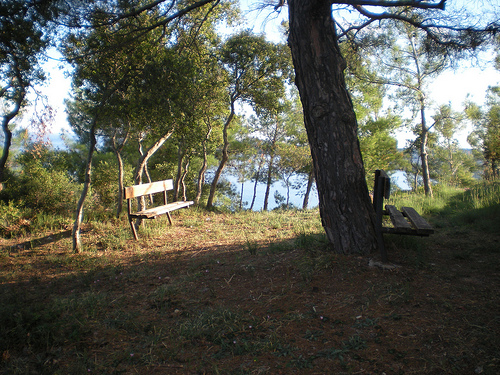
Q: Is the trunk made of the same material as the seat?
A: Yes, both the trunk and the seat are made of wood.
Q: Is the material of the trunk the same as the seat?
A: Yes, both the trunk and the seat are made of wood.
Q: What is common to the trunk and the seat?
A: The material, both the trunk and the seat are wooden.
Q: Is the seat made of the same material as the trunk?
A: Yes, both the seat and the trunk are made of wood.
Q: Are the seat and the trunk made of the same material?
A: Yes, both the seat and the trunk are made of wood.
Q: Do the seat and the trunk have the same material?
A: Yes, both the seat and the trunk are made of wood.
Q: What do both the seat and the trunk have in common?
A: The material, both the seat and the trunk are wooden.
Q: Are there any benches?
A: Yes, there is a bench.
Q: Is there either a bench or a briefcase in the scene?
A: Yes, there is a bench.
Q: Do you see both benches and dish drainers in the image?
A: No, there is a bench but no dish drainers.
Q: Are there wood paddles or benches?
A: Yes, there is a wood bench.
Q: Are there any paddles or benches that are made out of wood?
A: Yes, the bench is made of wood.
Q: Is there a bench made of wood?
A: Yes, there is a bench that is made of wood.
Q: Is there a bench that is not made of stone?
A: Yes, there is a bench that is made of wood.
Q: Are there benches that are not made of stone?
A: Yes, there is a bench that is made of wood.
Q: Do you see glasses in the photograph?
A: No, there are no glasses.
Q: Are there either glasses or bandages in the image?
A: No, there are no glasses or bandages.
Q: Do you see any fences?
A: No, there are no fences.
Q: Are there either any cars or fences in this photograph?
A: No, there are no fences or cars.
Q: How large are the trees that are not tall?
A: The trees are small.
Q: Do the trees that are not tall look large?
A: No, the trees are small.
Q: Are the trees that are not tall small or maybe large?
A: The trees are small.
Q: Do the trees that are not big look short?
A: Yes, the trees are short.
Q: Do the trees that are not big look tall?
A: No, the trees are short.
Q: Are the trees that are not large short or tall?
A: The trees are short.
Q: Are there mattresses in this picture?
A: No, there are no mattresses.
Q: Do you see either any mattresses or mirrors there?
A: No, there are no mattresses or mirrors.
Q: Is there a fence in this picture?
A: No, there are no fences.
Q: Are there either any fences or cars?
A: No, there are no fences or cars.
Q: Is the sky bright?
A: Yes, the sky is bright.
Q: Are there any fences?
A: No, there are no fences.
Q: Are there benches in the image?
A: Yes, there is a bench.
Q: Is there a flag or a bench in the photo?
A: Yes, there is a bench.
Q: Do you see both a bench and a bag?
A: No, there is a bench but no bags.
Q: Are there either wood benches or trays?
A: Yes, there is a wood bench.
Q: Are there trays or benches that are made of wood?
A: Yes, the bench is made of wood.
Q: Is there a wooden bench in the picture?
A: Yes, there is a wood bench.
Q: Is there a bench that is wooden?
A: Yes, there is a bench that is wooden.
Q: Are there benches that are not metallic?
A: Yes, there is a wooden bench.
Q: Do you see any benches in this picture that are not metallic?
A: Yes, there is a wooden bench.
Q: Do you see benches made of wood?
A: Yes, there is a bench that is made of wood.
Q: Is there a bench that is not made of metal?
A: Yes, there is a bench that is made of wood.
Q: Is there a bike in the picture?
A: No, there are no bikes.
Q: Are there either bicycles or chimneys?
A: No, there are no bicycles or chimneys.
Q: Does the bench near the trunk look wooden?
A: Yes, the bench is wooden.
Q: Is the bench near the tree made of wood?
A: Yes, the bench is made of wood.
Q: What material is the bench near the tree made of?
A: The bench is made of wood.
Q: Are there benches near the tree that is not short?
A: Yes, there is a bench near the tree.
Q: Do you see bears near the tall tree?
A: No, there is a bench near the tree.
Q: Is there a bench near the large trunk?
A: Yes, there is a bench near the trunk.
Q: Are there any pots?
A: No, there are no pots.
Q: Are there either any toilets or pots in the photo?
A: No, there are no pots or toilets.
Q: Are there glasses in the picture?
A: No, there are no glasses.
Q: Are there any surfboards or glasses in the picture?
A: No, there are no glasses or surfboards.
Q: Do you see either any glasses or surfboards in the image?
A: No, there are no glasses or surfboards.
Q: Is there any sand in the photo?
A: Yes, there is sand.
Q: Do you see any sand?
A: Yes, there is sand.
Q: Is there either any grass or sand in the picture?
A: Yes, there is sand.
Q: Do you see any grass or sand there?
A: Yes, there is sand.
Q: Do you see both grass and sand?
A: Yes, there are both sand and grass.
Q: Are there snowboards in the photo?
A: No, there are no snowboards.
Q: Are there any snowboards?
A: No, there are no snowboards.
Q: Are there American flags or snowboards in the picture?
A: No, there are no snowboards or American flags.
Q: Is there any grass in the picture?
A: Yes, there is grass.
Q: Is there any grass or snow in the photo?
A: Yes, there is grass.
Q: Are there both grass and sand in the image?
A: Yes, there are both grass and sand.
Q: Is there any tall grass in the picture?
A: Yes, there is tall grass.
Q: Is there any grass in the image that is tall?
A: Yes, there is grass that is tall.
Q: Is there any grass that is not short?
A: Yes, there is tall grass.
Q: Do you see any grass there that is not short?
A: Yes, there is tall grass.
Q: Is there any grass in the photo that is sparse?
A: Yes, there is sparse grass.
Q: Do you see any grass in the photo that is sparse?
A: Yes, there is grass that is sparse.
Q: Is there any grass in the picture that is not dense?
A: Yes, there is sparse grass.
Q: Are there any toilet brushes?
A: No, there are no toilet brushes.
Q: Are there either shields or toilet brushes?
A: No, there are no toilet brushes or shields.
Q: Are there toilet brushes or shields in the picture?
A: No, there are no toilet brushes or shields.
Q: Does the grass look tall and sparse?
A: Yes, the grass is tall and sparse.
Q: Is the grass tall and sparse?
A: Yes, the grass is tall and sparse.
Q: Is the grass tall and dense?
A: No, the grass is tall but sparse.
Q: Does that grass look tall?
A: Yes, the grass is tall.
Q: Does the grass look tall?
A: Yes, the grass is tall.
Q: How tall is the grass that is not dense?
A: The grass is tall.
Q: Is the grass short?
A: No, the grass is tall.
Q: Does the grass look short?
A: No, the grass is tall.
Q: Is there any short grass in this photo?
A: No, there is grass but it is tall.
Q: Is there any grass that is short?
A: No, there is grass but it is tall.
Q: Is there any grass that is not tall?
A: No, there is grass but it is tall.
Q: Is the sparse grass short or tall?
A: The grass is tall.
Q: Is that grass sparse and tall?
A: Yes, the grass is sparse and tall.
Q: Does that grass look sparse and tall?
A: Yes, the grass is sparse and tall.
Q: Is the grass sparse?
A: Yes, the grass is sparse.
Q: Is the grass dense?
A: No, the grass is sparse.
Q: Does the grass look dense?
A: No, the grass is sparse.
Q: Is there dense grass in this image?
A: No, there is grass but it is sparse.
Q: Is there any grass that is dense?
A: No, there is grass but it is sparse.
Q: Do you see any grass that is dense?
A: No, there is grass but it is sparse.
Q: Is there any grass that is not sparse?
A: No, there is grass but it is sparse.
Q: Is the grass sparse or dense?
A: The grass is sparse.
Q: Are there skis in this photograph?
A: No, there are no skis.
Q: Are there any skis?
A: No, there are no skis.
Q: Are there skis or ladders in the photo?
A: No, there are no skis or ladders.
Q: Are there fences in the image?
A: No, there are no fences.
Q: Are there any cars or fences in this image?
A: No, there are no fences or cars.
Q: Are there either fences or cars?
A: No, there are no fences or cars.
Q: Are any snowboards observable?
A: No, there are no snowboards.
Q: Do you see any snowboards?
A: No, there are no snowboards.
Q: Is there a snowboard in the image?
A: No, there are no snowboards.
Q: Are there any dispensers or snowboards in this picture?
A: No, there are no snowboards or dispensers.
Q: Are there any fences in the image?
A: No, there are no fences.